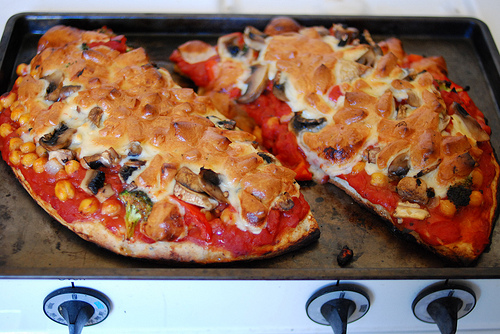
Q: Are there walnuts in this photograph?
A: No, there are no walnuts.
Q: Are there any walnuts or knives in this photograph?
A: No, there are no walnuts or knives.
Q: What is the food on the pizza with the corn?
A: The food is a mushroom.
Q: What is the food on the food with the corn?
A: The food is a mushroom.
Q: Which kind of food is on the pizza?
A: The food is a mushroom.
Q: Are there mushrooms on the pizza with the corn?
A: Yes, there is a mushroom on the pizza.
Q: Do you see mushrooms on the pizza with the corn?
A: Yes, there is a mushroom on the pizza.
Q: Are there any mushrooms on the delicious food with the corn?
A: Yes, there is a mushroom on the pizza.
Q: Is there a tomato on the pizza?
A: No, there is a mushroom on the pizza.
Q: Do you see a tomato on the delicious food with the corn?
A: No, there is a mushroom on the pizza.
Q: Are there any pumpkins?
A: No, there are no pumpkins.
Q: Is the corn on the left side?
A: Yes, the corn is on the left of the image.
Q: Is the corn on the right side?
A: No, the corn is on the left of the image.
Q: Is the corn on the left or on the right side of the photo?
A: The corn is on the left of the image.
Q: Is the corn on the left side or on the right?
A: The corn is on the left of the image.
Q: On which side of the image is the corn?
A: The corn is on the left of the image.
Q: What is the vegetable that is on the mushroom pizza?
A: The vegetable is corn.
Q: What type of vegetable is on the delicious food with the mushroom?
A: The vegetable is corn.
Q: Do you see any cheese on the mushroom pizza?
A: No, there is corn on the pizza.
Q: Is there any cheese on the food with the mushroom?
A: No, there is corn on the pizza.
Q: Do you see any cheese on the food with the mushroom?
A: No, there is corn on the pizza.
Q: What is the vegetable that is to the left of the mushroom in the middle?
A: The vegetable is corn.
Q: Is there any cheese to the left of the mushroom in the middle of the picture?
A: No, there is corn to the left of the mushroom.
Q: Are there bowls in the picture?
A: No, there are no bowls.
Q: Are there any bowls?
A: No, there are no bowls.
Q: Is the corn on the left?
A: Yes, the corn is on the left of the image.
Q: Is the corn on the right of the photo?
A: No, the corn is on the left of the image.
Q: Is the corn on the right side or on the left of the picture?
A: The corn is on the left of the image.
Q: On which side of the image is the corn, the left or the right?
A: The corn is on the left of the image.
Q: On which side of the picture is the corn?
A: The corn is on the left of the image.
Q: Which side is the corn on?
A: The corn is on the left of the image.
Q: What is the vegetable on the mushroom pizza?
A: The vegetable is corn.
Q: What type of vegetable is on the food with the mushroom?
A: The vegetable is corn.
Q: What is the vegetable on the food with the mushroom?
A: The vegetable is corn.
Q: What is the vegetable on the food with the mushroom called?
A: The vegetable is corn.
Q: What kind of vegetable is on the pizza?
A: The vegetable is corn.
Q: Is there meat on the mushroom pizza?
A: No, there is corn on the pizza.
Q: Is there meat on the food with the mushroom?
A: No, there is corn on the pizza.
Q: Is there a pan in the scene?
A: Yes, there is a pan.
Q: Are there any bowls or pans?
A: Yes, there is a pan.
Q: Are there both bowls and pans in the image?
A: No, there is a pan but no bowls.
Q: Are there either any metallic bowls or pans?
A: Yes, there is a metal pan.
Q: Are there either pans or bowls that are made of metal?
A: Yes, the pan is made of metal.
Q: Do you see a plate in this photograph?
A: No, there are no plates.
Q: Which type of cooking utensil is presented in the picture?
A: The cooking utensil is a pan.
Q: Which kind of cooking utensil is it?
A: The cooking utensil is a pan.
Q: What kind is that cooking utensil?
A: This is a pan.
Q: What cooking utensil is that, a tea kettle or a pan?
A: This is a pan.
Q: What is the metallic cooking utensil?
A: The cooking utensil is a pan.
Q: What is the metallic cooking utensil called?
A: The cooking utensil is a pan.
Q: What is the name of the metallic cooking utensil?
A: The cooking utensil is a pan.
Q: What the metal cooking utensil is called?
A: The cooking utensil is a pan.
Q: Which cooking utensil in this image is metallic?
A: The cooking utensil is a pan.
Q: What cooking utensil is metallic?
A: The cooking utensil is a pan.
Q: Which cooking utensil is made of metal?
A: The cooking utensil is a pan.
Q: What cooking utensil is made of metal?
A: The cooking utensil is a pan.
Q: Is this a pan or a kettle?
A: This is a pan.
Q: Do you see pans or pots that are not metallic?
A: No, there is a pan but it is metallic.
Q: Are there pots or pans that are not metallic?
A: No, there is a pan but it is metallic.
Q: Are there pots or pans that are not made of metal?
A: No, there is a pan but it is made of metal.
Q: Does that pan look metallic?
A: Yes, the pan is metallic.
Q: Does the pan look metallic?
A: Yes, the pan is metallic.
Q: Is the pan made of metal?
A: Yes, the pan is made of metal.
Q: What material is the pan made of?
A: The pan is made of metal.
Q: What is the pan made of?
A: The pan is made of metal.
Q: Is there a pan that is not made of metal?
A: No, there is a pan but it is made of metal.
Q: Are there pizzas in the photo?
A: Yes, there is a pizza.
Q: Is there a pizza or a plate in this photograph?
A: Yes, there is a pizza.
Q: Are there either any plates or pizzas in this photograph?
A: Yes, there is a pizza.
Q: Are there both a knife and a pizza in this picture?
A: No, there is a pizza but no knives.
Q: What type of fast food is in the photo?
A: The fast food is a pizza.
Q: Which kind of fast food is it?
A: The food is a pizza.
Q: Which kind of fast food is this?
A: That is a pizza.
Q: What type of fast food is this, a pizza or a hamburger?
A: That is a pizza.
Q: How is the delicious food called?
A: The food is a pizza.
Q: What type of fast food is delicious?
A: The fast food is a pizza.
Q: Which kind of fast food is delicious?
A: The fast food is a pizza.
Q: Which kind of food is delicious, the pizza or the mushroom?
A: The pizza is delicious.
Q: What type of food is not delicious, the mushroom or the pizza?
A: The mushroom is not delicious.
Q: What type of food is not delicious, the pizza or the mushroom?
A: The mushroom is not delicious.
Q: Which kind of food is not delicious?
A: The food is a mushroom.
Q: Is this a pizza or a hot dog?
A: This is a pizza.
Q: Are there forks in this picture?
A: No, there are no forks.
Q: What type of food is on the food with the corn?
A: The food is a mushroom.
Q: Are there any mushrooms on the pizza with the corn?
A: Yes, there is a mushroom on the pizza.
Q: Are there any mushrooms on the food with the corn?
A: Yes, there is a mushroom on the pizza.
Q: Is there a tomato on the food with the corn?
A: No, there is a mushroom on the pizza.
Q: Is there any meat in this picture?
A: No, there is no meat.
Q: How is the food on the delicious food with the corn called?
A: The food is a mushroom.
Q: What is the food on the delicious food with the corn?
A: The food is a mushroom.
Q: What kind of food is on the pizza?
A: The food is a mushroom.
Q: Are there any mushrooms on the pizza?
A: Yes, there is a mushroom on the pizza.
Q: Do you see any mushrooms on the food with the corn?
A: Yes, there is a mushroom on the pizza.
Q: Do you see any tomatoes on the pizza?
A: No, there is a mushroom on the pizza.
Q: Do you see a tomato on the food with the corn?
A: No, there is a mushroom on the pizza.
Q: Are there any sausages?
A: No, there are no sausages.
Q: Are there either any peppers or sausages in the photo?
A: No, there are no sausages or peppers.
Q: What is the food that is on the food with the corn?
A: The food is a mushroom.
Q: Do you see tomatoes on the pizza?
A: No, there is a mushroom on the pizza.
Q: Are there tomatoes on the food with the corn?
A: No, there is a mushroom on the pizza.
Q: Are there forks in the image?
A: No, there are no forks.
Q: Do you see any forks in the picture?
A: No, there are no forks.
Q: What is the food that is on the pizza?
A: The food is a mushroom.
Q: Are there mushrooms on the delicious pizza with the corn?
A: Yes, there is a mushroom on the pizza.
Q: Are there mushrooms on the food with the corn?
A: Yes, there is a mushroom on the pizza.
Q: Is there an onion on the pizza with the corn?
A: No, there is a mushroom on the pizza.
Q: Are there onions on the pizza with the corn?
A: No, there is a mushroom on the pizza.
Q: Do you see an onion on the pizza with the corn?
A: No, there is a mushroom on the pizza.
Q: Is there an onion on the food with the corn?
A: No, there is a mushroom on the pizza.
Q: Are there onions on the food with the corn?
A: No, there is a mushroom on the pizza.